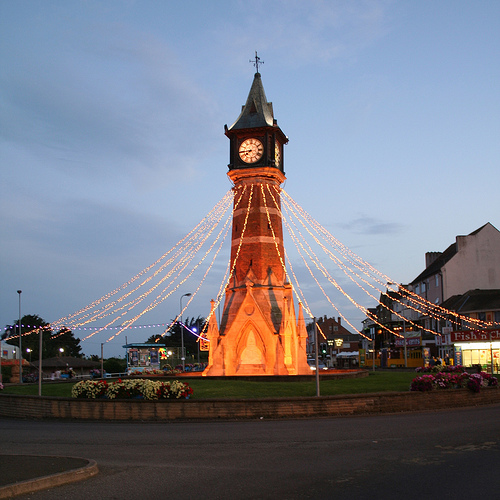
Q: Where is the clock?
A: Toward the top of the tower.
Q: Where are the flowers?
A: Along the outside edge of the green.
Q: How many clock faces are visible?
A: Two.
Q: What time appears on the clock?
A: 7:45.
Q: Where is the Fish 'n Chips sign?
A: On the storefront to the right of the green.